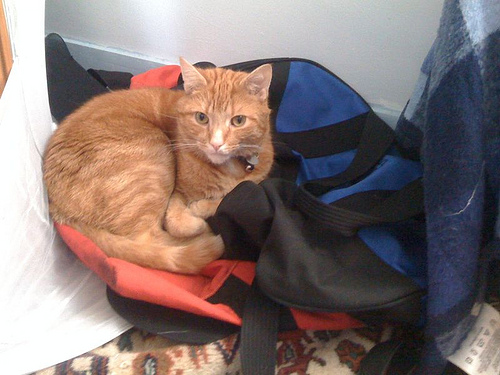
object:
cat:
[41, 56, 274, 279]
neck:
[183, 141, 267, 169]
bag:
[219, 58, 427, 336]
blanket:
[395, 1, 499, 372]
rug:
[28, 326, 392, 375]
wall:
[47, 2, 443, 112]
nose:
[212, 134, 224, 147]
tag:
[447, 301, 499, 375]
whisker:
[239, 146, 275, 155]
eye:
[233, 116, 246, 126]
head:
[176, 66, 272, 165]